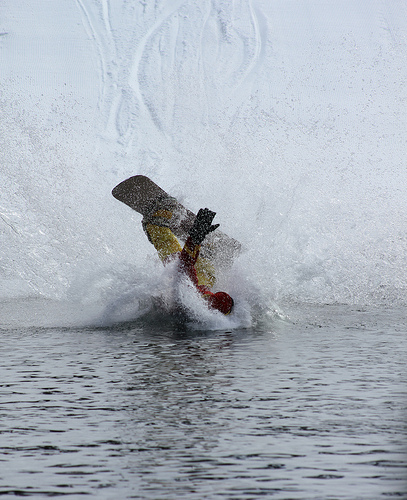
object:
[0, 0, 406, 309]
incline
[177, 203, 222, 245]
glove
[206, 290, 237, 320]
head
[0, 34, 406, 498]
water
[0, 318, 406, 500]
ripples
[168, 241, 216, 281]
arm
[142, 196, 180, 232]
boots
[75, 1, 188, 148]
tracks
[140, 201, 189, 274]
yellow pants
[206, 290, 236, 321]
hat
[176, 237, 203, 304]
sleeve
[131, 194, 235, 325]
man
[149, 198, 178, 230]
feet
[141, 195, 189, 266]
leg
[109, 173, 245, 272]
board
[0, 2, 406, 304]
snow